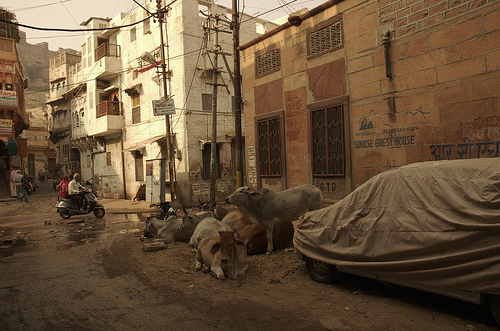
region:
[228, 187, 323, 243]
white cow in street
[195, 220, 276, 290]
white cow laying on road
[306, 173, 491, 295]
white cover on car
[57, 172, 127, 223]
people on small moped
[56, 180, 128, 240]
small moped on dirt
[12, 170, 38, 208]
people on dirt road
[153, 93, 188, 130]
white sign on pole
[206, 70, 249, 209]
tall pole behind cow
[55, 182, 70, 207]
red shirt on woman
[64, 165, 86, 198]
white shirt on man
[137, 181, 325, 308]
cows on the side of the building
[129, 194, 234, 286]
cows laying on the ground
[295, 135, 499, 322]
a white cover over the car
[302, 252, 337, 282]
the tire from under the cover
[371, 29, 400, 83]
a pipe on the wall of the building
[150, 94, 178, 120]
a white sign on the pool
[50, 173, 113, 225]
the man and women on the bike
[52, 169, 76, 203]
the women in a red outfit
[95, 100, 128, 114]
the red fence on the building balcony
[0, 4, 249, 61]
power lines hanging over the dirt road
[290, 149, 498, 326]
A car wrapped in canvas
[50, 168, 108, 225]
A man riding a moped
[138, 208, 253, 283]
Cows laying in a street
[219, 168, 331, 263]
A cow standing beside a building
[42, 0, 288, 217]
An apartment building in a city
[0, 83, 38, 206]
Two men walking into a store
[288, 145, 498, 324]
A vehicle parked beside a building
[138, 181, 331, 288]
Cows in the middle of a city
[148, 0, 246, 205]
Telephone poles between two buildings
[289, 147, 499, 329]
A car with a flat tire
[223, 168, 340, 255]
cow in the street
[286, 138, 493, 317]
car covered on side of road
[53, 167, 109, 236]
man on a motor bike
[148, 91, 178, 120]
sign on a pole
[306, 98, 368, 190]
window on a building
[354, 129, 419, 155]
blue writing on a building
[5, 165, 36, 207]
people walking in the street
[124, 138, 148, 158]
awning over a window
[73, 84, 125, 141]
balcony on a building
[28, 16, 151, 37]
electrical wire above street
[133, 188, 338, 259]
There is a herd of cows.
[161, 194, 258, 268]
The cows are lying down.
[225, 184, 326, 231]
The cow is standing up.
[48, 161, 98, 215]
Two people on a moped.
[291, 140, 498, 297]
Tarp over the car.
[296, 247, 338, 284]
The tire is showing.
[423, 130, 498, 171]
Graffiti on the building.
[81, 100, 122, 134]
Balcony on the building.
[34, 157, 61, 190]
People driving mopeds in the distance.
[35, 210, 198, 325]
The street is wet.